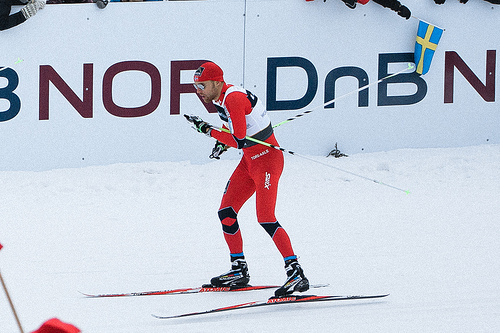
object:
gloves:
[206, 140, 228, 160]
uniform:
[189, 61, 313, 299]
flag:
[412, 18, 445, 77]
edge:
[413, 19, 421, 68]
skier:
[74, 55, 424, 323]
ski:
[77, 279, 338, 300]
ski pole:
[180, 111, 420, 196]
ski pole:
[269, 62, 420, 130]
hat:
[189, 60, 226, 82]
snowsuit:
[212, 83, 298, 259]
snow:
[0, 142, 500, 330]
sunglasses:
[187, 81, 210, 91]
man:
[182, 58, 312, 300]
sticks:
[182, 64, 422, 197]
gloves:
[182, 112, 216, 135]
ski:
[148, 291, 393, 330]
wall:
[0, 1, 498, 177]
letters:
[36, 61, 99, 123]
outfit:
[180, 112, 413, 196]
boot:
[272, 256, 312, 301]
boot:
[209, 260, 252, 290]